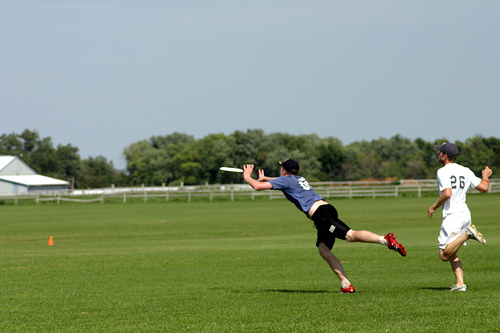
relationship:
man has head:
[241, 157, 407, 294] [267, 145, 305, 183]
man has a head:
[424, 141, 494, 294] [435, 141, 458, 164]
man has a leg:
[241, 157, 407, 294] [342, 225, 392, 257]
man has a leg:
[241, 157, 407, 294] [356, 224, 447, 266]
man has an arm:
[403, 115, 485, 245] [481, 162, 493, 199]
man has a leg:
[229, 149, 416, 298] [434, 221, 486, 261]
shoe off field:
[382, 233, 410, 253] [0, 185, 500, 333]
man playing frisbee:
[241, 157, 407, 294] [217, 163, 245, 174]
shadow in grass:
[213, 283, 338, 295] [1, 190, 498, 331]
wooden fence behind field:
[2, 178, 499, 203] [0, 193, 498, 330]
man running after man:
[424, 141, 494, 294] [241, 157, 407, 294]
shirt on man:
[267, 150, 343, 238] [171, 122, 425, 309]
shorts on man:
[310, 203, 351, 251] [229, 128, 405, 319]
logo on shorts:
[327, 223, 341, 233] [308, 200, 350, 249]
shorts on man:
[308, 200, 350, 249] [241, 157, 407, 294]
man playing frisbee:
[241, 157, 407, 294] [198, 147, 260, 194]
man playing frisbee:
[424, 141, 494, 294] [198, 147, 260, 194]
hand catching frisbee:
[242, 164, 254, 176] [221, 164, 243, 176]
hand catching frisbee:
[257, 167, 267, 177] [221, 164, 243, 176]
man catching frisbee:
[241, 157, 407, 294] [220, 165, 243, 172]